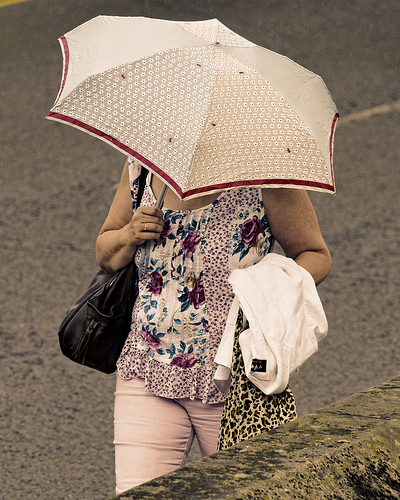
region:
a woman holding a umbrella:
[87, 24, 338, 264]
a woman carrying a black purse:
[47, 119, 183, 439]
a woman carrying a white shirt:
[208, 223, 336, 383]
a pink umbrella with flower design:
[82, 61, 318, 225]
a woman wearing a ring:
[142, 217, 154, 239]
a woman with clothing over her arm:
[212, 226, 327, 390]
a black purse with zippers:
[52, 260, 142, 380]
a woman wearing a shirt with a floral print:
[77, 189, 289, 443]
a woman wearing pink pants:
[128, 378, 188, 499]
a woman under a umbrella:
[41, 64, 367, 300]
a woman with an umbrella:
[28, 30, 368, 471]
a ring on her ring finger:
[143, 213, 153, 232]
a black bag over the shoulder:
[46, 165, 169, 386]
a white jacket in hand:
[194, 257, 355, 417]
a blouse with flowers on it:
[119, 174, 271, 395]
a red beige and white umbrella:
[58, 12, 364, 218]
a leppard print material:
[224, 322, 305, 456]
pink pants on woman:
[89, 350, 305, 491]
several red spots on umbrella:
[119, 60, 308, 172]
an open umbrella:
[40, 9, 375, 193]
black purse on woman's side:
[27, 287, 148, 394]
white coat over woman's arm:
[213, 261, 337, 389]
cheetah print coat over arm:
[209, 358, 298, 448]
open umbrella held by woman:
[44, 17, 398, 218]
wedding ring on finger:
[139, 209, 157, 229]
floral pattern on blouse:
[150, 230, 227, 372]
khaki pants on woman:
[71, 375, 193, 466]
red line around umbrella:
[159, 173, 268, 201]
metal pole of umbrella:
[146, 181, 189, 218]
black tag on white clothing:
[248, 361, 286, 374]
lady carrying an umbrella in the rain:
[33, 24, 385, 481]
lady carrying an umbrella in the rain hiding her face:
[38, 16, 358, 267]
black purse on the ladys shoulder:
[47, 163, 175, 364]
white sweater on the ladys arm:
[210, 266, 346, 415]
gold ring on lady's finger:
[142, 219, 149, 231]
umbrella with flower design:
[54, 20, 348, 201]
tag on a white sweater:
[246, 349, 276, 377]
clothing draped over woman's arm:
[213, 253, 328, 427]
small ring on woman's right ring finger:
[142, 220, 147, 231]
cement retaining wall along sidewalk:
[109, 376, 398, 498]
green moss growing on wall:
[361, 433, 387, 453]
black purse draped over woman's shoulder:
[57, 163, 148, 374]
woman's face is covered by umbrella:
[42, 15, 341, 203]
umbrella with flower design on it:
[44, 15, 340, 204]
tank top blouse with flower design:
[122, 158, 271, 402]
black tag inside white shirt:
[249, 357, 267, 374]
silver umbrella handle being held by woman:
[153, 176, 170, 207]